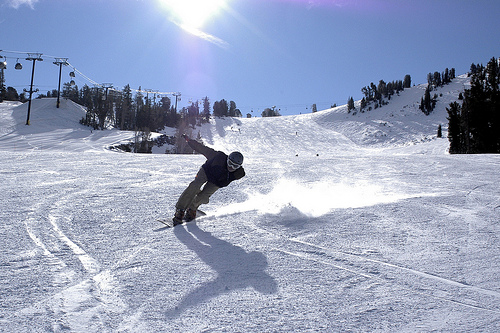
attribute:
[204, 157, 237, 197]
jacket — black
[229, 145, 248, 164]
helmet — gray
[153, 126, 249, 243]
man — snowboarding, leaning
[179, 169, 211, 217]
pants — khaki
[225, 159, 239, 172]
goggles — white